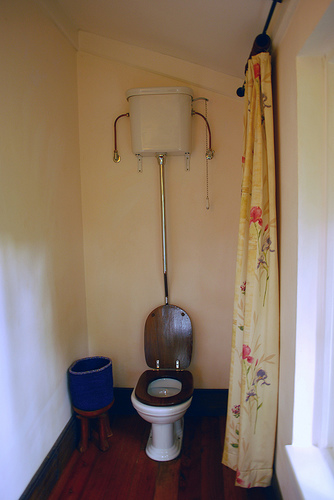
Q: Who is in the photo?
A: No one.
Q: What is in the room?
A: A toilet.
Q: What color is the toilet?
A: Brown and white.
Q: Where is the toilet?
A: In the room.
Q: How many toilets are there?
A: One.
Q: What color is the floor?
A: Brown.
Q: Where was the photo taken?
A: In a bathroom.